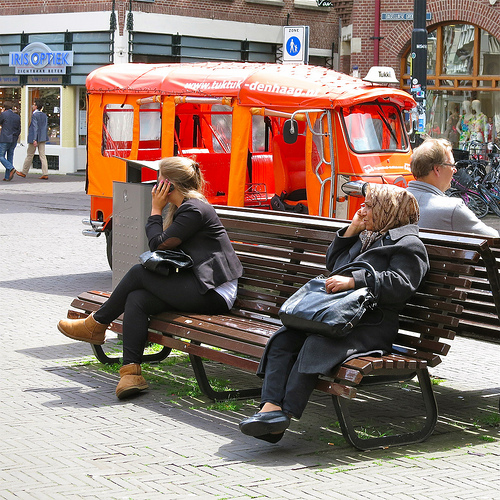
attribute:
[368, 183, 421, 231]
scarf — brown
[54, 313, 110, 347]
boot — brown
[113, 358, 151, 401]
boot — brown